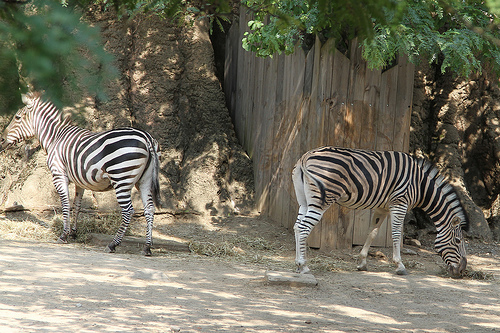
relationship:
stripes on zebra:
[312, 157, 428, 195] [292, 147, 474, 299]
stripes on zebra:
[302, 152, 430, 198] [273, 147, 498, 310]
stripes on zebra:
[302, 152, 430, 198] [0, 86, 166, 256]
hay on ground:
[190, 219, 285, 261] [34, 205, 389, 332]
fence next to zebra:
[227, 6, 419, 250] [290, 146, 468, 279]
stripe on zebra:
[104, 151, 151, 164] [281, 140, 481, 290]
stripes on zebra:
[312, 156, 430, 211] [265, 133, 459, 258]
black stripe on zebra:
[112, 180, 134, 189] [0, 86, 166, 256]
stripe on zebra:
[94, 138, 137, 158] [290, 146, 468, 279]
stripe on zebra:
[305, 155, 363, 206] [290, 146, 468, 279]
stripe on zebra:
[298, 246, 305, 254] [290, 146, 468, 279]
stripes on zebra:
[309, 194, 333, 204] [290, 146, 468, 279]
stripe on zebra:
[308, 207, 322, 214] [290, 146, 468, 279]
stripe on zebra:
[303, 213, 320, 221] [290, 146, 468, 279]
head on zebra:
[1, 89, 43, 148] [0, 86, 166, 256]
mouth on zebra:
[0, 130, 14, 152] [0, 86, 166, 256]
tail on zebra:
[141, 133, 177, 218] [0, 82, 159, 242]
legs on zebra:
[101, 149, 163, 261] [0, 86, 166, 256]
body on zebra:
[16, 107, 193, 261] [10, 77, 186, 238]